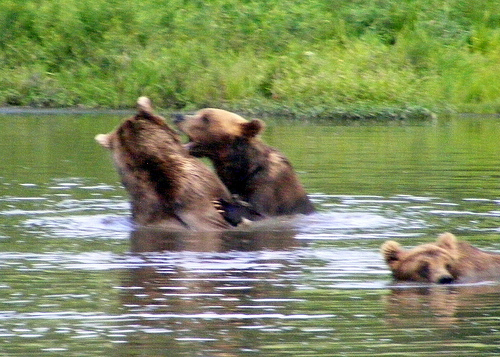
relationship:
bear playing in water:
[381, 230, 498, 284] [1, 109, 497, 355]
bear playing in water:
[171, 100, 317, 216] [1, 109, 497, 355]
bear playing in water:
[96, 96, 229, 228] [1, 109, 497, 355]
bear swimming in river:
[381, 230, 498, 284] [1, 109, 497, 355]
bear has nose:
[171, 100, 317, 216] [172, 112, 185, 123]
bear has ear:
[96, 96, 229, 228] [136, 96, 155, 116]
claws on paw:
[211, 196, 227, 214] [225, 199, 249, 223]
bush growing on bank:
[39, 15, 70, 66] [33, 76, 158, 116]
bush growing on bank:
[82, 35, 104, 71] [33, 76, 158, 116]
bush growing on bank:
[117, 28, 143, 64] [33, 76, 158, 116]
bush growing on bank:
[150, 31, 167, 59] [33, 76, 158, 116]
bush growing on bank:
[174, 45, 198, 73] [33, 76, 158, 116]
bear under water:
[381, 230, 498, 284] [1, 109, 497, 355]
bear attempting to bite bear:
[171, 100, 317, 216] [96, 96, 229, 228]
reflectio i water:
[384, 278, 499, 341] [1, 109, 497, 355]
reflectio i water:
[230, 210, 320, 294] [1, 109, 497, 355]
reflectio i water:
[129, 208, 233, 289] [1, 109, 497, 355]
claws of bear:
[211, 196, 227, 214] [96, 96, 229, 228]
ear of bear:
[136, 96, 155, 116] [96, 96, 229, 228]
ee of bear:
[202, 115, 210, 125] [171, 100, 317, 216]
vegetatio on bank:
[2, 0, 498, 109] [33, 76, 158, 116]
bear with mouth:
[171, 100, 317, 216] [171, 120, 202, 152]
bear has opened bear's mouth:
[171, 100, 317, 216] [174, 114, 197, 149]